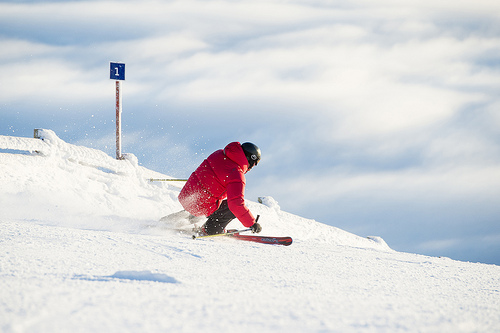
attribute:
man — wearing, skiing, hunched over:
[192, 137, 339, 321]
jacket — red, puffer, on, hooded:
[180, 143, 270, 220]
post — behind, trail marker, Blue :
[94, 52, 178, 180]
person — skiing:
[112, 101, 306, 258]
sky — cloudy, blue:
[254, 40, 433, 151]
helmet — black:
[223, 131, 262, 164]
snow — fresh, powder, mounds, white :
[42, 224, 316, 327]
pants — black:
[148, 180, 278, 240]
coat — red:
[142, 90, 269, 251]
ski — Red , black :
[222, 226, 318, 252]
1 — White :
[88, 44, 147, 83]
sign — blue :
[94, 56, 164, 116]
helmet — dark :
[233, 123, 283, 171]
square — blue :
[99, 41, 147, 105]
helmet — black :
[243, 130, 290, 187]